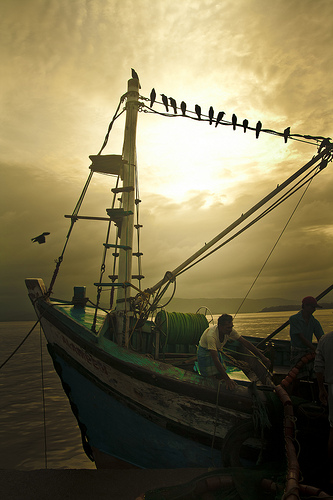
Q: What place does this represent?
A: It represents the ocean.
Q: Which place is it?
A: It is an ocean.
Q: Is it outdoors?
A: Yes, it is outdoors.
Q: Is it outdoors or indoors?
A: It is outdoors.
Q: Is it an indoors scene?
A: No, it is outdoors.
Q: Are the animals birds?
A: Yes, all the animals are birds.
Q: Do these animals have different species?
A: No, all the animals are birds.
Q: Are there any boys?
A: No, there are no boys.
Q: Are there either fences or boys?
A: No, there are no boys or fences.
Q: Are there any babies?
A: No, there are no babies.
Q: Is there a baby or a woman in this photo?
A: No, there are no babies or women.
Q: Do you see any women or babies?
A: No, there are no babies or women.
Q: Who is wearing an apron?
A: The man is wearing an apron.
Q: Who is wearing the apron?
A: The man is wearing an apron.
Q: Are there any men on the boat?
A: Yes, there is a man on the boat.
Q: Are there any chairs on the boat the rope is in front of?
A: No, there is a man on the boat.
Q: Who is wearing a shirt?
A: The man is wearing a shirt.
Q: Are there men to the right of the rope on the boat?
A: Yes, there is a man to the right of the rope.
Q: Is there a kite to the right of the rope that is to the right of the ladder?
A: No, there is a man to the right of the rope.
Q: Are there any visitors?
A: No, there are no visitors.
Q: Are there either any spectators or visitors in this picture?
A: No, there are no visitors or spectators.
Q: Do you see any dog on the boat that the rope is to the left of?
A: No, there is a man on the boat.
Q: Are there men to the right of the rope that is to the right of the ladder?
A: Yes, there is a man to the right of the rope.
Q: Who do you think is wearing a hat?
A: The man is wearing a hat.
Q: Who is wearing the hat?
A: The man is wearing a hat.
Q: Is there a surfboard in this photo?
A: No, there are no surfboards.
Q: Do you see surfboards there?
A: No, there are no surfboards.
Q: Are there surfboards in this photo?
A: No, there are no surfboards.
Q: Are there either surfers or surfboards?
A: No, there are no surfboards or surfers.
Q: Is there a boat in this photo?
A: Yes, there is a boat.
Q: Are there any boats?
A: Yes, there is a boat.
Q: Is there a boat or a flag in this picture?
A: Yes, there is a boat.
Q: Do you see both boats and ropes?
A: Yes, there are both a boat and a rope.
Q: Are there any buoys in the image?
A: No, there are no buoys.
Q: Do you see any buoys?
A: No, there are no buoys.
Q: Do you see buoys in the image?
A: No, there are no buoys.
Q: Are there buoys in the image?
A: No, there are no buoys.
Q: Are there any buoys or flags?
A: No, there are no buoys or flags.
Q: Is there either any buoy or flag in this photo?
A: No, there are no buoys or flags.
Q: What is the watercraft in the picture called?
A: The watercraft is a boat.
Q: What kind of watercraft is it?
A: The watercraft is a boat.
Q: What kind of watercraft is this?
A: That is a boat.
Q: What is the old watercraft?
A: The watercraft is a boat.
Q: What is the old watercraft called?
A: The watercraft is a boat.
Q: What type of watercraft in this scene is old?
A: The watercraft is a boat.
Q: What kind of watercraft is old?
A: The watercraft is a boat.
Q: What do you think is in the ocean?
A: The boat is in the ocean.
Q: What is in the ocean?
A: The boat is in the ocean.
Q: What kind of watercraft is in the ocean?
A: The watercraft is a boat.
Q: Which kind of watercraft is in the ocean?
A: The watercraft is a boat.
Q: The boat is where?
A: The boat is in the ocean.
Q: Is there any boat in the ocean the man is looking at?
A: Yes, there is a boat in the ocean.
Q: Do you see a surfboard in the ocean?
A: No, there is a boat in the ocean.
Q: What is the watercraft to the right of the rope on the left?
A: The watercraft is a boat.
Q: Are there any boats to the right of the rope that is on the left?
A: Yes, there is a boat to the right of the rope.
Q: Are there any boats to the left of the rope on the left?
A: No, the boat is to the right of the rope.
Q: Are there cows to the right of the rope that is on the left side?
A: No, there is a boat to the right of the rope.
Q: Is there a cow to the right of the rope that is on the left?
A: No, there is a boat to the right of the rope.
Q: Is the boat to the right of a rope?
A: Yes, the boat is to the right of a rope.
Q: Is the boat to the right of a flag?
A: No, the boat is to the right of a rope.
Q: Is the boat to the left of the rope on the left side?
A: No, the boat is to the right of the rope.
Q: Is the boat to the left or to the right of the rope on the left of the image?
A: The boat is to the right of the rope.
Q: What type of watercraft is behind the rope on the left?
A: The watercraft is a boat.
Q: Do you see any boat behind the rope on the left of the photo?
A: Yes, there is a boat behind the rope.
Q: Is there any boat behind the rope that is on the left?
A: Yes, there is a boat behind the rope.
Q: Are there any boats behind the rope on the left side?
A: Yes, there is a boat behind the rope.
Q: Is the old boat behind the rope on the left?
A: Yes, the boat is behind the rope.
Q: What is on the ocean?
A: The boat is on the ocean.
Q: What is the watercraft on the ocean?
A: The watercraft is a boat.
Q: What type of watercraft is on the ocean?
A: The watercraft is a boat.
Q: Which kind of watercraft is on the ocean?
A: The watercraft is a boat.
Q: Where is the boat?
A: The boat is on the ocean.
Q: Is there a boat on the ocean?
A: Yes, there is a boat on the ocean.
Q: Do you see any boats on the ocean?
A: Yes, there is a boat on the ocean.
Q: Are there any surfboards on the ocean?
A: No, there is a boat on the ocean.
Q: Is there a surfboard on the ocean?
A: No, there is a boat on the ocean.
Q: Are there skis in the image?
A: No, there are no skis.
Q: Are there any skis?
A: No, there are no skis.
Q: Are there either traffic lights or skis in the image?
A: No, there are no skis or traffic lights.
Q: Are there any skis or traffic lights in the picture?
A: No, there are no skis or traffic lights.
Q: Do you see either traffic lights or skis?
A: No, there are no skis or traffic lights.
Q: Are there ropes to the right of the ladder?
A: Yes, there is a rope to the right of the ladder.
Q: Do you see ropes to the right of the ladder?
A: Yes, there is a rope to the right of the ladder.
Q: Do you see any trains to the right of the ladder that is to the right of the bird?
A: No, there is a rope to the right of the ladder.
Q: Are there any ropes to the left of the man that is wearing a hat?
A: Yes, there is a rope to the left of the man.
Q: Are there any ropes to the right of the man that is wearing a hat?
A: No, the rope is to the left of the man.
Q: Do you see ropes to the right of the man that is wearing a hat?
A: No, the rope is to the left of the man.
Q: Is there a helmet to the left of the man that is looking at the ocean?
A: No, there is a rope to the left of the man.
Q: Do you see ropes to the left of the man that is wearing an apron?
A: Yes, there is a rope to the left of the man.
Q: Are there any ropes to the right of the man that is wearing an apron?
A: No, the rope is to the left of the man.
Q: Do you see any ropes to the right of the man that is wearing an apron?
A: No, the rope is to the left of the man.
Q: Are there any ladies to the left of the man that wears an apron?
A: No, there is a rope to the left of the man.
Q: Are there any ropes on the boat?
A: Yes, there is a rope on the boat.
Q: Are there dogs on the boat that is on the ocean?
A: No, there is a rope on the boat.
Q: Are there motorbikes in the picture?
A: No, there are no motorbikes.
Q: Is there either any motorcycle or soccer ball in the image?
A: No, there are no motorcycles or soccer balls.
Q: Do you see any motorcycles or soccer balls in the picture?
A: No, there are no motorcycles or soccer balls.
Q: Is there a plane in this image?
A: No, there are no airplanes.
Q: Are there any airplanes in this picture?
A: No, there are no airplanes.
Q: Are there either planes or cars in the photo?
A: No, there are no planes or cars.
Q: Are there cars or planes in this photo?
A: No, there are no planes or cars.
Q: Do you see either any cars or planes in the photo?
A: No, there are no planes or cars.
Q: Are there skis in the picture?
A: No, there are no skis.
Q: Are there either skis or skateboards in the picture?
A: No, there are no skis or skateboards.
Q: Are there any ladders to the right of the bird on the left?
A: Yes, there is a ladder to the right of the bird.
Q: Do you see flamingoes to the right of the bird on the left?
A: No, there is a ladder to the right of the bird.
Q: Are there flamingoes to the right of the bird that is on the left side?
A: No, there is a ladder to the right of the bird.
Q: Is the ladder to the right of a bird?
A: Yes, the ladder is to the right of a bird.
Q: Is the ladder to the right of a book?
A: No, the ladder is to the right of a bird.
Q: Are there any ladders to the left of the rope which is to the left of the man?
A: Yes, there is a ladder to the left of the rope.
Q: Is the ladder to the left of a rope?
A: Yes, the ladder is to the left of a rope.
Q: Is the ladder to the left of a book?
A: No, the ladder is to the left of a rope.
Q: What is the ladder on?
A: The ladder is on the boat.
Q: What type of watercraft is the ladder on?
A: The ladder is on the boat.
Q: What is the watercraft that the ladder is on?
A: The watercraft is a boat.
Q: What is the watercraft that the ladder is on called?
A: The watercraft is a boat.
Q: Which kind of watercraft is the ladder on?
A: The ladder is on the boat.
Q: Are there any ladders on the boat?
A: Yes, there is a ladder on the boat.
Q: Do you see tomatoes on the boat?
A: No, there is a ladder on the boat.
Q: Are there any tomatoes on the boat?
A: No, there is a ladder on the boat.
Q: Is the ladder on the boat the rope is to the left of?
A: Yes, the ladder is on the boat.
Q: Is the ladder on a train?
A: No, the ladder is on the boat.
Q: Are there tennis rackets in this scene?
A: No, there are no tennis rackets.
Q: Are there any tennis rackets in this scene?
A: No, there are no tennis rackets.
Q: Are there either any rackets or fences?
A: No, there are no rackets or fences.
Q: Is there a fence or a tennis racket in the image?
A: No, there are no rackets or fences.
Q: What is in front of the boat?
A: The rope is in front of the boat.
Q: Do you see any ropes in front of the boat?
A: Yes, there is a rope in front of the boat.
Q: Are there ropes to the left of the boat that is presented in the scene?
A: Yes, there is a rope to the left of the boat.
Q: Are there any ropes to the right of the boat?
A: No, the rope is to the left of the boat.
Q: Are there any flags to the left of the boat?
A: No, there is a rope to the left of the boat.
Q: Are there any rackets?
A: No, there are no rackets.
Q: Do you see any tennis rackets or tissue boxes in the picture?
A: No, there are no tennis rackets or tissue boxes.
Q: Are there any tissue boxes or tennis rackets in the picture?
A: No, there are no tennis rackets or tissue boxes.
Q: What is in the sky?
A: The sun is in the sky.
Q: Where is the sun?
A: The sun is in the sky.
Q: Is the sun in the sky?
A: Yes, the sun is in the sky.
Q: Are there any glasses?
A: No, there are no glasses.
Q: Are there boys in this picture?
A: No, there are no boys.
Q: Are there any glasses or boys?
A: No, there are no boys or glasses.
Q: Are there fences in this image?
A: No, there are no fences.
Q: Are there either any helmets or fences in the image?
A: No, there are no fences or helmets.